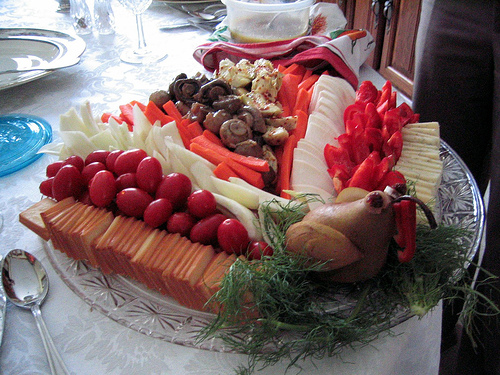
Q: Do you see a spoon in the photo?
A: Yes, there is a spoon.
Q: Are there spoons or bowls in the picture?
A: Yes, there is a spoon.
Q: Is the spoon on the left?
A: Yes, the spoon is on the left of the image.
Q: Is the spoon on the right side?
A: No, the spoon is on the left of the image.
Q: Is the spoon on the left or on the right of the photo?
A: The spoon is on the left of the image.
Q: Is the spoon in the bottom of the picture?
A: Yes, the spoon is in the bottom of the image.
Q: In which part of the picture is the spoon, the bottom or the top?
A: The spoon is in the bottom of the image.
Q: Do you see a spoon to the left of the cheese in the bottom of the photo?
A: Yes, there is a spoon to the left of the cheese.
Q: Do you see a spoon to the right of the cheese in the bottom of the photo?
A: No, the spoon is to the left of the cheese.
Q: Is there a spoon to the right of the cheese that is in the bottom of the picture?
A: No, the spoon is to the left of the cheese.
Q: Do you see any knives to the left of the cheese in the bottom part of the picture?
A: No, there is a spoon to the left of the cheese.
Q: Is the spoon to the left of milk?
A: No, the spoon is to the left of the cheese.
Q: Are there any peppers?
A: Yes, there are peppers.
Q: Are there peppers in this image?
A: Yes, there are peppers.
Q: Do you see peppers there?
A: Yes, there are peppers.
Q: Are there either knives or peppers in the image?
A: Yes, there are peppers.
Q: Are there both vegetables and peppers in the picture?
A: Yes, there are both peppers and vegetables.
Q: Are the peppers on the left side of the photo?
A: No, the peppers are on the right of the image.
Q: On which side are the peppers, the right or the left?
A: The peppers are on the right of the image.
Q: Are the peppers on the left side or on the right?
A: The peppers are on the right of the image.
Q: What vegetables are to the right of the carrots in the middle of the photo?
A: The vegetables are peppers.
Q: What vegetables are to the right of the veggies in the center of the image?
A: The vegetables are peppers.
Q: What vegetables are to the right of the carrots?
A: The vegetables are peppers.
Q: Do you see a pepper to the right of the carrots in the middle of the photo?
A: Yes, there are peppers to the right of the carrots.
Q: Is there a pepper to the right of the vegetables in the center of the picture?
A: Yes, there are peppers to the right of the carrots.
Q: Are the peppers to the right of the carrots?
A: Yes, the peppers are to the right of the carrots.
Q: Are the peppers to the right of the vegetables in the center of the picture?
A: Yes, the peppers are to the right of the carrots.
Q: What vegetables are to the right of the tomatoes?
A: The vegetables are peppers.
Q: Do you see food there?
A: Yes, there is food.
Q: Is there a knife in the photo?
A: No, there are no knives.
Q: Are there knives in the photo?
A: No, there are no knives.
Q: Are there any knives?
A: No, there are no knives.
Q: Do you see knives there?
A: No, there are no knives.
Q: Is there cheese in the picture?
A: Yes, there is cheese.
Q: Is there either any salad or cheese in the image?
A: Yes, there is cheese.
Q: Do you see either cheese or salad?
A: Yes, there is cheese.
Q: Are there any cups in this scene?
A: No, there are no cups.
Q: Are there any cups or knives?
A: No, there are no cups or knives.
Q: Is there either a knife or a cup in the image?
A: No, there are no cups or knives.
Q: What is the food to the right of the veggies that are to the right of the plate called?
A: The food is cheese.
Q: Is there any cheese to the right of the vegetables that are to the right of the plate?
A: Yes, there is cheese to the right of the veggies.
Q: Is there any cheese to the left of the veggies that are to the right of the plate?
A: No, the cheese is to the right of the vegetables.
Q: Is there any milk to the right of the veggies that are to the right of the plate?
A: No, there is cheese to the right of the vegetables.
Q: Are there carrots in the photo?
A: Yes, there are carrots.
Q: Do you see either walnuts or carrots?
A: Yes, there are carrots.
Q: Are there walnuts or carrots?
A: Yes, there are carrots.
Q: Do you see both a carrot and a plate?
A: Yes, there are both a carrot and a plate.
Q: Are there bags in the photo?
A: No, there are no bags.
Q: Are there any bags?
A: No, there are no bags.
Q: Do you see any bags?
A: No, there are no bags.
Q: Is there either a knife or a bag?
A: No, there are no bags or knives.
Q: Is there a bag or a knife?
A: No, there are no bags or knives.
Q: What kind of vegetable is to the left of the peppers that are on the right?
A: The vegetables are carrots.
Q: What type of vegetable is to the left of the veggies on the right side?
A: The vegetables are carrots.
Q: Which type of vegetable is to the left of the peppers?
A: The vegetables are carrots.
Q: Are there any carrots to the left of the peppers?
A: Yes, there are carrots to the left of the peppers.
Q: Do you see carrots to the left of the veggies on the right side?
A: Yes, there are carrots to the left of the peppers.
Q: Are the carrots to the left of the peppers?
A: Yes, the carrots are to the left of the peppers.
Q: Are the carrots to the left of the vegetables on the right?
A: Yes, the carrots are to the left of the peppers.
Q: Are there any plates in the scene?
A: Yes, there is a plate.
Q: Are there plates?
A: Yes, there is a plate.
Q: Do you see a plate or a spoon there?
A: Yes, there is a plate.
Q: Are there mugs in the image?
A: No, there are no mugs.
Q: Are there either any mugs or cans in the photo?
A: No, there are no mugs or cans.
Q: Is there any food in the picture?
A: Yes, there is food.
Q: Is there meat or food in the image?
A: Yes, there is food.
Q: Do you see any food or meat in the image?
A: Yes, there is food.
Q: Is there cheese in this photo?
A: Yes, there is cheese.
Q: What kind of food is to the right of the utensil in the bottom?
A: The food is cheese.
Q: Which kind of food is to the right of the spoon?
A: The food is cheese.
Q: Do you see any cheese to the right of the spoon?
A: Yes, there is cheese to the right of the spoon.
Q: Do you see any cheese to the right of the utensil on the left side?
A: Yes, there is cheese to the right of the spoon.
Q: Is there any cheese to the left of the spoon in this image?
A: No, the cheese is to the right of the spoon.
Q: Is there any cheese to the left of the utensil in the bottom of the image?
A: No, the cheese is to the right of the spoon.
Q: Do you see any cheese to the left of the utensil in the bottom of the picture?
A: No, the cheese is to the right of the spoon.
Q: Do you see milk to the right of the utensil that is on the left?
A: No, there is cheese to the right of the spoon.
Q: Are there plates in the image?
A: Yes, there is a plate.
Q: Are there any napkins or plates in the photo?
A: Yes, there is a plate.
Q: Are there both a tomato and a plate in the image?
A: Yes, there are both a plate and a tomato.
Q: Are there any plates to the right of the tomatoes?
A: Yes, there is a plate to the right of the tomatoes.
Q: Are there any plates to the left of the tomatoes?
A: No, the plate is to the right of the tomatoes.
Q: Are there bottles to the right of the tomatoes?
A: No, there is a plate to the right of the tomatoes.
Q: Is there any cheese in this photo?
A: Yes, there is cheese.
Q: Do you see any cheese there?
A: Yes, there is cheese.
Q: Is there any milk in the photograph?
A: No, there is no milk.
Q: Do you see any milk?
A: No, there is no milk.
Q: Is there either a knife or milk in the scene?
A: No, there are no milk or knives.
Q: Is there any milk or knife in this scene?
A: No, there are no milk or knives.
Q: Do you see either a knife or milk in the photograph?
A: No, there are no milk or knives.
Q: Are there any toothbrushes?
A: No, there are no toothbrushes.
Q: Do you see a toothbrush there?
A: No, there are no toothbrushes.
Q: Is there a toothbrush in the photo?
A: No, there are no toothbrushes.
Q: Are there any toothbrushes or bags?
A: No, there are no toothbrushes or bags.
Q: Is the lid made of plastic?
A: Yes, the lid is made of plastic.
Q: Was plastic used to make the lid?
A: Yes, the lid is made of plastic.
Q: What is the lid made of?
A: The lid is made of plastic.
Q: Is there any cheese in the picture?
A: Yes, there is cheese.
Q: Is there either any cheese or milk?
A: Yes, there is cheese.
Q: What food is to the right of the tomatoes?
A: The food is cheese.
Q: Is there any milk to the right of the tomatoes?
A: No, there is cheese to the right of the tomatoes.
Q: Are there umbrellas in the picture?
A: No, there are no umbrellas.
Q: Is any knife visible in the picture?
A: No, there are no knives.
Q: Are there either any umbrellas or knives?
A: No, there are no knives or umbrellas.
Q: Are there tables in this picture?
A: Yes, there is a table.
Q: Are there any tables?
A: Yes, there is a table.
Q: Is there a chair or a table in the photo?
A: Yes, there is a table.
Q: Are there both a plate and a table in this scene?
A: Yes, there are both a table and a plate.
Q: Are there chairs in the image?
A: No, there are no chairs.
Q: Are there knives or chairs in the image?
A: No, there are no chairs or knives.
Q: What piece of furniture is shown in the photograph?
A: The piece of furniture is a table.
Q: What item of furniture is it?
A: The piece of furniture is a table.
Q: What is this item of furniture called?
A: This is a table.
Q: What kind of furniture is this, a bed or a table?
A: This is a table.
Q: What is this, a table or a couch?
A: This is a table.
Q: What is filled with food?
A: The table is filled with food.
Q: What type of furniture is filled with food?
A: The piece of furniture is a table.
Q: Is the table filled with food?
A: Yes, the table is filled with food.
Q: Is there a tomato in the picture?
A: Yes, there are tomatoes.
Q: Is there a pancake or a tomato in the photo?
A: Yes, there are tomatoes.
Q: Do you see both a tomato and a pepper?
A: Yes, there are both a tomato and a pepper.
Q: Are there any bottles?
A: No, there are no bottles.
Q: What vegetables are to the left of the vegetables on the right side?
A: The vegetables are tomatoes.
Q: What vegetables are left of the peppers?
A: The vegetables are tomatoes.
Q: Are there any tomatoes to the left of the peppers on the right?
A: Yes, there are tomatoes to the left of the peppers.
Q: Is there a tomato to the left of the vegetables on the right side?
A: Yes, there are tomatoes to the left of the peppers.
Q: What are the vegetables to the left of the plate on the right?
A: The vegetables are tomatoes.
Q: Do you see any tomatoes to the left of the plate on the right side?
A: Yes, there are tomatoes to the left of the plate.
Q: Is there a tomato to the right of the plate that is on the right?
A: No, the tomatoes are to the left of the plate.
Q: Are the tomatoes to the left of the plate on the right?
A: Yes, the tomatoes are to the left of the plate.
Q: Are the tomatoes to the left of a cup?
A: No, the tomatoes are to the left of the plate.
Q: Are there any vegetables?
A: Yes, there are vegetables.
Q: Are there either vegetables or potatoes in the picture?
A: Yes, there are vegetables.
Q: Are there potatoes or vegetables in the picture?
A: Yes, there are vegetables.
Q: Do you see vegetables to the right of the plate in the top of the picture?
A: Yes, there are vegetables to the right of the plate.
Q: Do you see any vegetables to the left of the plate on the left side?
A: No, the vegetables are to the right of the plate.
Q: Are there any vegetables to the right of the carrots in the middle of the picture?
A: Yes, there are vegetables to the right of the carrots.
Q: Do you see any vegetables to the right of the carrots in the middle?
A: Yes, there are vegetables to the right of the carrots.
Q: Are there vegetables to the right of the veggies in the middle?
A: Yes, there are vegetables to the right of the carrots.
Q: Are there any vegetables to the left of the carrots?
A: No, the vegetables are to the right of the carrots.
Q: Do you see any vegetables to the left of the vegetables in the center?
A: No, the vegetables are to the right of the carrots.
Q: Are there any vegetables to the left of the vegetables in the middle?
A: No, the vegetables are to the right of the carrots.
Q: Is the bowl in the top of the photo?
A: Yes, the bowl is in the top of the image.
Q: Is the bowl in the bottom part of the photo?
A: No, the bowl is in the top of the image.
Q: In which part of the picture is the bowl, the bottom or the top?
A: The bowl is in the top of the image.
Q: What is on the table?
A: The bowl is on the table.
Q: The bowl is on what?
A: The bowl is on the table.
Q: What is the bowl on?
A: The bowl is on the table.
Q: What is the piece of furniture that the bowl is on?
A: The piece of furniture is a table.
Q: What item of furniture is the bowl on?
A: The bowl is on the table.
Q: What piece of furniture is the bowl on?
A: The bowl is on the table.